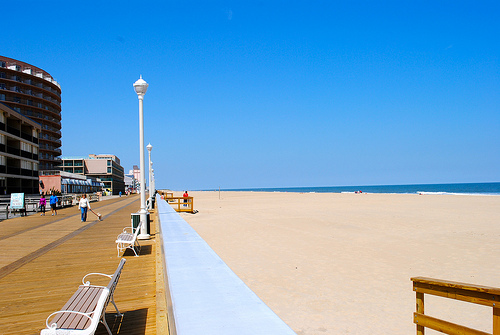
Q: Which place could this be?
A: It is a beach.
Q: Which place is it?
A: It is a beach.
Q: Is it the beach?
A: Yes, it is the beach.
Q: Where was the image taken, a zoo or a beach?
A: It was taken at a beach.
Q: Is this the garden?
A: No, it is the beach.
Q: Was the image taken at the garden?
A: No, the picture was taken in the beach.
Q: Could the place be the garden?
A: No, it is the beach.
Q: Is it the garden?
A: No, it is the beach.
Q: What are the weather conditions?
A: It is clear.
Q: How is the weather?
A: It is clear.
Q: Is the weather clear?
A: Yes, it is clear.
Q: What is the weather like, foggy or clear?
A: It is clear.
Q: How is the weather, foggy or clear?
A: It is clear.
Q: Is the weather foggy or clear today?
A: It is clear.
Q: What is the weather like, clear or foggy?
A: It is clear.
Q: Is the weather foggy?
A: No, it is clear.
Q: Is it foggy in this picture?
A: No, it is clear.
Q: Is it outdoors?
A: Yes, it is outdoors.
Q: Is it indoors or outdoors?
A: It is outdoors.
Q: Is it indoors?
A: No, it is outdoors.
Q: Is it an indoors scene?
A: No, it is outdoors.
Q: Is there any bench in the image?
A: Yes, there is a bench.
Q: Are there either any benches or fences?
A: Yes, there is a bench.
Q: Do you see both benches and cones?
A: No, there is a bench but no cones.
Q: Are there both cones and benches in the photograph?
A: No, there is a bench but no cones.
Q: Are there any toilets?
A: No, there are no toilets.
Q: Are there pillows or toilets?
A: No, there are no toilets or pillows.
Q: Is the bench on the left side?
A: Yes, the bench is on the left of the image.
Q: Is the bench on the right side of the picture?
A: No, the bench is on the left of the image.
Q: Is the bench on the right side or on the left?
A: The bench is on the left of the image.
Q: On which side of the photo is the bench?
A: The bench is on the left of the image.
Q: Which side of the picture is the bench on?
A: The bench is on the left of the image.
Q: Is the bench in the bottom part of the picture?
A: Yes, the bench is in the bottom of the image.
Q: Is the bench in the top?
A: No, the bench is in the bottom of the image.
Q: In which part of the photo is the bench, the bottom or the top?
A: The bench is in the bottom of the image.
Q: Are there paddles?
A: No, there are no paddles.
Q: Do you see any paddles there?
A: No, there are no paddles.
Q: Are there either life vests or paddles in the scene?
A: No, there are no paddles or life vests.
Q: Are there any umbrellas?
A: No, there are no umbrellas.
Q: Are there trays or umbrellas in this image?
A: No, there are no umbrellas or trays.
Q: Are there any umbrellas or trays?
A: No, there are no umbrellas or trays.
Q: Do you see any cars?
A: No, there are no cars.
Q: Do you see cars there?
A: No, there are no cars.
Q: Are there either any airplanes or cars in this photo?
A: No, there are no cars or airplanes.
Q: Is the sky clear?
A: Yes, the sky is clear.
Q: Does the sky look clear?
A: Yes, the sky is clear.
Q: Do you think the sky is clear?
A: Yes, the sky is clear.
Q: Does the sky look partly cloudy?
A: No, the sky is clear.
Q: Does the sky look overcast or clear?
A: The sky is clear.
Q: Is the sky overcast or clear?
A: The sky is clear.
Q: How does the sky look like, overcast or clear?
A: The sky is clear.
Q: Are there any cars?
A: No, there are no cars.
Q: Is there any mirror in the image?
A: No, there are no mirrors.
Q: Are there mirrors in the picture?
A: No, there are no mirrors.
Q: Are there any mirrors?
A: No, there are no mirrors.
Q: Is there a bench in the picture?
A: Yes, there is a bench.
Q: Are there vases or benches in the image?
A: Yes, there is a bench.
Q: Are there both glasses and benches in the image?
A: No, there is a bench but no glasses.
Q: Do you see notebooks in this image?
A: No, there are no notebooks.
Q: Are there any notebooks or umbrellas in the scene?
A: No, there are no notebooks or umbrellas.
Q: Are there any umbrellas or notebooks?
A: No, there are no notebooks or umbrellas.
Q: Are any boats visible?
A: No, there are no boats.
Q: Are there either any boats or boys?
A: No, there are no boats or boys.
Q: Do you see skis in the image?
A: No, there are no skis.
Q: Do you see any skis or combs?
A: No, there are no skis or combs.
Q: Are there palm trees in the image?
A: No, there are no palm trees.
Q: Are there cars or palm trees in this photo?
A: No, there are no palm trees or cars.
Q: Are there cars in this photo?
A: No, there are no cars.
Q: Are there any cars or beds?
A: No, there are no cars or beds.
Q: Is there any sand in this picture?
A: Yes, there is sand.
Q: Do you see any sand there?
A: Yes, there is sand.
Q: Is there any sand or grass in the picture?
A: Yes, there is sand.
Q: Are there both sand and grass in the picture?
A: No, there is sand but no grass.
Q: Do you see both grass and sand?
A: No, there is sand but no grass.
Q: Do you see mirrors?
A: No, there are no mirrors.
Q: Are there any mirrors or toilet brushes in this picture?
A: No, there are no mirrors or toilet brushes.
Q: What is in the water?
A: The sand is in the water.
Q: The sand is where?
A: The sand is in the water.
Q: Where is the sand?
A: The sand is in the water.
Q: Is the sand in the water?
A: Yes, the sand is in the water.